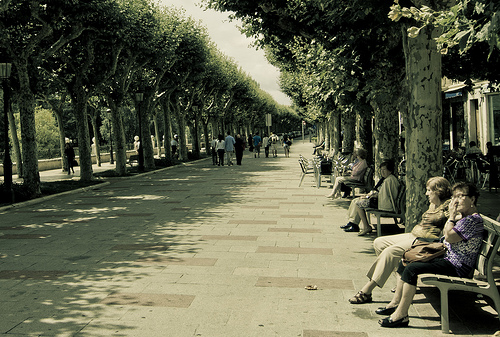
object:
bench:
[343, 164, 375, 198]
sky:
[208, 16, 265, 56]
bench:
[415, 212, 498, 333]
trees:
[0, 0, 204, 194]